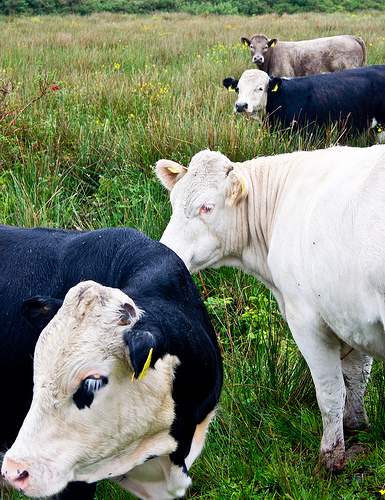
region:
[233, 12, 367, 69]
Brown cow in the field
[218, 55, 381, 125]
Black and white cow in a field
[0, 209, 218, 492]
Black and white cow in a field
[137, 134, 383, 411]
White cow in a field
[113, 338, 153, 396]
Yellow tag on cows ear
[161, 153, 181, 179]
Yellow tag on cows ear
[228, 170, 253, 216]
Yellow tag on cows ear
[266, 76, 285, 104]
Yellow tag on cows ear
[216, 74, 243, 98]
Yellow tag on cows ear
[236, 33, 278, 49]
Yellow tag on cows ear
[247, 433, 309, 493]
green grass on the ground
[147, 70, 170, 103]
yellow dandelion flowers on ground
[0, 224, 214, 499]
black and white cow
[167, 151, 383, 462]
white cow standing on grass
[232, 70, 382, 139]
black and white cow sitting in background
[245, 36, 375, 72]
brown cow standing outside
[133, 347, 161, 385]
yellow tag on black cow's left ear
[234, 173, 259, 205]
yellow clip on white cow's left ear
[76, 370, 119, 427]
left eye on black and white cow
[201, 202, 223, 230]
left eye on white cow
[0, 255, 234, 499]
a cow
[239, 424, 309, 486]
the green grass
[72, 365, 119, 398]
the cows eye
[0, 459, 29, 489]
the cows nose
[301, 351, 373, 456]
the cows legs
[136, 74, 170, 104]
yellow flowers in the grass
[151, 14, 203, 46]
dead grass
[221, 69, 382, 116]
a black and white cow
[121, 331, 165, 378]
the cows ear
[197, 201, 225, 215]
the animals eye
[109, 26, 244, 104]
yellow flowers blooming in field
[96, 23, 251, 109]
small clusters of yellow flowers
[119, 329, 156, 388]
cow has tag for identification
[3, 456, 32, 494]
cow has pink nose with black spots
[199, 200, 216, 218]
white cow has pink eyes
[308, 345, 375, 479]
white feet are covered with mud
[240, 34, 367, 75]
brown cow has tags on both ears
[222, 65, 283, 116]
black cow with a black nose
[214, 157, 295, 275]
animal has lots of wrinkles around neck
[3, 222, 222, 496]
black cow with a white head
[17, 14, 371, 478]
a group of cattle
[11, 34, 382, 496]
a herd of cattle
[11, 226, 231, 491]
a black and white cow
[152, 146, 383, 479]
a white cow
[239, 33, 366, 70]
a brown cow in a field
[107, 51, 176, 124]
yellow flowers in a field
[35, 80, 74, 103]
red flowers in a field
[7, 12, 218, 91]
brown and green grasses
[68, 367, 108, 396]
a eye of a cow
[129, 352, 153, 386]
a yellow tag in a ear